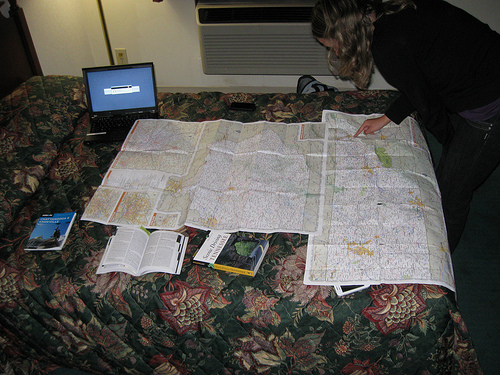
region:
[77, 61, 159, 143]
open laptop computer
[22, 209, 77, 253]
a travel guide book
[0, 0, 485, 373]
a full size hotel bed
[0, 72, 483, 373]
green colorful quilted bed spread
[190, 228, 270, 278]
a travel guide book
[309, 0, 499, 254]
an adult female with long hair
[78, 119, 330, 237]
an open travel map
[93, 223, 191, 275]
an open travel guide book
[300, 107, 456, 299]
an open travel map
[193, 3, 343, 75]
an air conditioning unit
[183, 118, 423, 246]
there is a map on the bed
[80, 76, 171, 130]
the laptop is on the bed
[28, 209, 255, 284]
there are three books on the bed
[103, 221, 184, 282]
one book is open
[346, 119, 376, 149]
she is pointing on the map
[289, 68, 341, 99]
there is a bag on the ground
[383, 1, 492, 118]
she has a black top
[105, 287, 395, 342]
the comforter has flower drawing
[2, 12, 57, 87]
the headboard is made of wood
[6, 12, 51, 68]
the headboard is brown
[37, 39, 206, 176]
Computers on the bed.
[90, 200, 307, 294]
Books on the bed.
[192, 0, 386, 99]
Air conditioner on the wall.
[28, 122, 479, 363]
Floral bed spread on the bed.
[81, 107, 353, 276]
Map on the bed.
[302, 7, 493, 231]
Woman standing by the bed.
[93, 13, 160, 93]
Light socket on the wall.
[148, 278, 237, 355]
Flower on the bed spread.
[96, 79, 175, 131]
White design on the screen.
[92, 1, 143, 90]
Part of a lamp post.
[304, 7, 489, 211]
a woman reading a map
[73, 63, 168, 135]
a laptop on the bed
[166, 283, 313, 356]
a floral comforter on the bed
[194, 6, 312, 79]
an air conditioner in the window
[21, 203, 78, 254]
a brochure on the bed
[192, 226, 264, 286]
a travel book lying on the bed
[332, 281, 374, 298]
a white cell phone under the map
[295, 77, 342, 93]
a back pack leaning against the wall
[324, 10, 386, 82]
brown hair hanging over a face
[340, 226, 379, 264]
yellow markings on the map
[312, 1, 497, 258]
Woman leaning over map on bed.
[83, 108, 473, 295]
Two maps spread over bed.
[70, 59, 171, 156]
Black laptop computer sitting on bed.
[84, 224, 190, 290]
Book laying open on bed.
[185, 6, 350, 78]
AC unit in wall.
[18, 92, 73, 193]
Flower print bedspread on bed.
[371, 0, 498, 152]
Woman dressed in black sweater.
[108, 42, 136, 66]
Electrical outlet on wall.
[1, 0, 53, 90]
Edge of a headboard.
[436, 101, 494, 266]
Woman dressed in gray jeans.